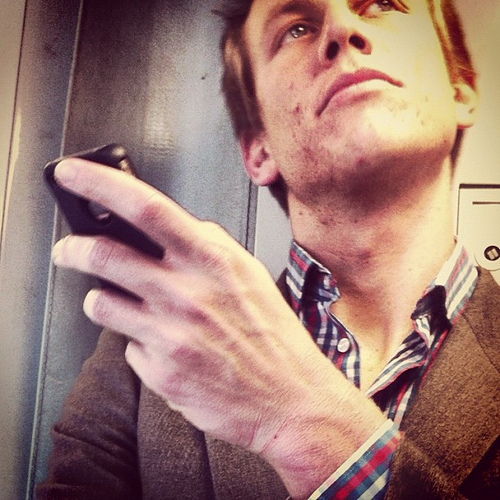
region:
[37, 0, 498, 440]
man holding a phone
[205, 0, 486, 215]
young man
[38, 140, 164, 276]
black cellphone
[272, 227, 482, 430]
checkered button down shirt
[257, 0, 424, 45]
blue eyes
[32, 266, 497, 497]
brown, wool sportscoat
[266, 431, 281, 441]
a brown freckle on a young man's wrist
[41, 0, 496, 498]
young man holding a black cellphone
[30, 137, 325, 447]
hand holding a cellphone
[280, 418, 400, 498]
cuff of a red, white, and blue checkered shirt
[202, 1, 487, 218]
a lone young man thinking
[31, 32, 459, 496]
man is holding the phone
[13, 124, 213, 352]
the phone is black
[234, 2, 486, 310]
man is looking up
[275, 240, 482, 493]
man is wearing shirt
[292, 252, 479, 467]
the shirt is plaid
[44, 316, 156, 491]
man is wearing coat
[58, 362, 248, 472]
the coat is brown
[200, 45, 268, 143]
the hair is brown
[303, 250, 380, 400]
the shirt has buttons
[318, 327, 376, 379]
the button is white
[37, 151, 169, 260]
The phone in the man's hand.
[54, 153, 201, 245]
The man's index finger.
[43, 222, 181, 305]
The man's middle finger.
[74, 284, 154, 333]
The man's index finger.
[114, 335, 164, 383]
The man's pinky finger.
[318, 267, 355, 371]
The white buttons on the man's plaid shirt.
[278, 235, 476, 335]
The collar of the man's plaid shirt.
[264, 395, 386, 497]
The wrist of the man.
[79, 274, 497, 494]
The blazer jacket the man is wearing.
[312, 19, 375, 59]
The nose and nostrils of the man in the plaid shirt.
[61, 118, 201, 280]
A man holding his cellphone.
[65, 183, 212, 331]
A man holding his cellphone.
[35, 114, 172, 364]
A man holding his cellphone.